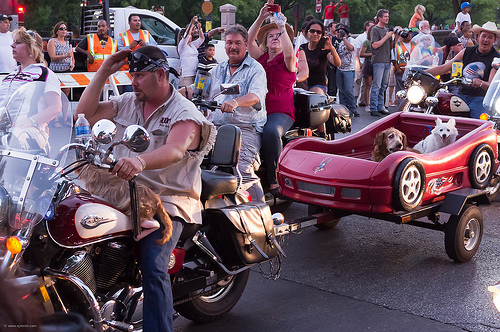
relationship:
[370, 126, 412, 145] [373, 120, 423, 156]
head of dog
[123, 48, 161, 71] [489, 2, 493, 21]
glasses of sun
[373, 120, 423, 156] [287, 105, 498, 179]
dog in car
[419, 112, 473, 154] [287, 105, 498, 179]
dog in car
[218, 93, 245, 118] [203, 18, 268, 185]
hand of man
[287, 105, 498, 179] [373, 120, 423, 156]
car for dog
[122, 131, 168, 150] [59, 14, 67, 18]
mirror for side view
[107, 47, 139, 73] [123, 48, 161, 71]
hand with glasses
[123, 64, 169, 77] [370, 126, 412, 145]
bandana on head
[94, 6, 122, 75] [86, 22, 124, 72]
man in vest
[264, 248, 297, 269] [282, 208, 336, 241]
chain on bar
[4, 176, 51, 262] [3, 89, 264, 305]
headlamp on motorcycle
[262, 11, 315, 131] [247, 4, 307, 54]
woman taking picture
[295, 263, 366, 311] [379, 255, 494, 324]
cracks in street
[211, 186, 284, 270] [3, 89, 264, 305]
bag on motorcycle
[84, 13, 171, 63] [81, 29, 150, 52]
men in vests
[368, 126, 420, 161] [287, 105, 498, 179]
dog in car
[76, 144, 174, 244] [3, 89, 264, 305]
dog on motorcycle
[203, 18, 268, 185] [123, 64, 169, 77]
man with bandana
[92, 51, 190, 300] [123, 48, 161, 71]
man with glasses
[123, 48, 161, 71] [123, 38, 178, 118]
glasses on head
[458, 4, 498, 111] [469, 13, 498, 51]
guy wearing cowboy hat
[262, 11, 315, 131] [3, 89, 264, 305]
woman on motorcycle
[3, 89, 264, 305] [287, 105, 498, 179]
motorcycle pulling car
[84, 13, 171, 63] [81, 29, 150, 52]
men with vests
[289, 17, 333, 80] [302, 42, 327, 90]
lady wearing t-shirt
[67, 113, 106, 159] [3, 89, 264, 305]
water on motorcycle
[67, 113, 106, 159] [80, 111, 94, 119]
water in bottle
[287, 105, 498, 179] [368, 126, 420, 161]
car with dog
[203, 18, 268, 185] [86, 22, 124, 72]
man wearing vest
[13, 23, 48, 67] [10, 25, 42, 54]
female has head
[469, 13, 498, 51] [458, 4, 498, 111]
cowboy hat on guy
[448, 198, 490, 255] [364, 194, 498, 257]
wheel on trailer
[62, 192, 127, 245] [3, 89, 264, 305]
tank on motorcycle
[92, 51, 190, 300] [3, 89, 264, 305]
man on motorcycle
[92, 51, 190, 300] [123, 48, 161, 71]
man holding glasses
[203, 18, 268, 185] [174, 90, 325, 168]
man on motorcycle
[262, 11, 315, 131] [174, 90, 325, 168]
woman on motorcycle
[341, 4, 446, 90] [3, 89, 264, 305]
people watching motorcycle